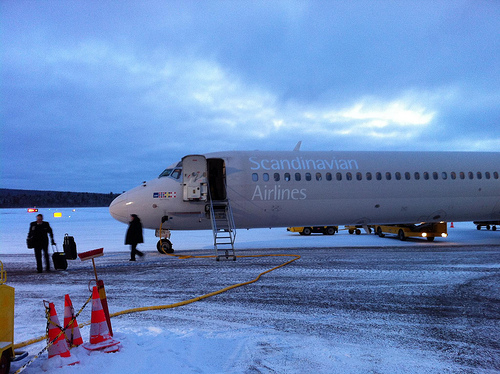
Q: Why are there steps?
A: To enter/ exit.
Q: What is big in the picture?
A: Airplane.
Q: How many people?
A: Two.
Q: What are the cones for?
A: Caution.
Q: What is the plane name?
A: Scandinavian Airlines.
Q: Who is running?
A: No one.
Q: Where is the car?
A: No car.